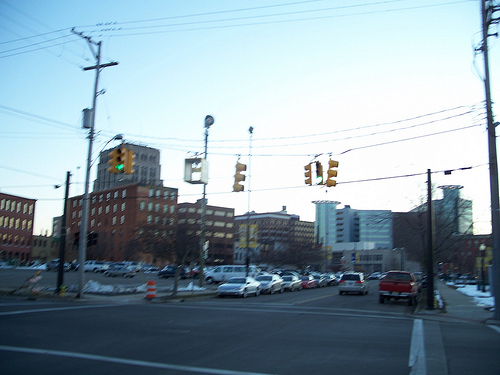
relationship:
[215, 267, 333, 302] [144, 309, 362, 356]
cars on street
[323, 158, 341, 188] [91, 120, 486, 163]
light hanging from wire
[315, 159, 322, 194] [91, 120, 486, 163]
light hanging from wire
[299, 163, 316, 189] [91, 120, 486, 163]
light hanging from wire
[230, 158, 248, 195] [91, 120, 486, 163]
light hanging from wire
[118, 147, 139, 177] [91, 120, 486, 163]
light hanging from wire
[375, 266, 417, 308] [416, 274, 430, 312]
truck parked at curb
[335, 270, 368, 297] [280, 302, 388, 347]
car driving down road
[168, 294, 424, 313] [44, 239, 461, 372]
line on road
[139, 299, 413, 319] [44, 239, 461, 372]
line on road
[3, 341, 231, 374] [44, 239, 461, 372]
line on road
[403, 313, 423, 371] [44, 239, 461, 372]
line on road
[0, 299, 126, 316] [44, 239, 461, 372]
line on road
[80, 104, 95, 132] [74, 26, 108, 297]
box on pole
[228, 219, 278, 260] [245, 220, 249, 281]
sign on pole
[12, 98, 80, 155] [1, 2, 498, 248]
clouds in sky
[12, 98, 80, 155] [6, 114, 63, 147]
clouds are white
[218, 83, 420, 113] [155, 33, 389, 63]
white cloud in blue sky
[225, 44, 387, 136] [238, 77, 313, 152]
clouds in sky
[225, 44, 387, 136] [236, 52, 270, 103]
clouds are blue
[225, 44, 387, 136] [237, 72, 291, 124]
clouds are white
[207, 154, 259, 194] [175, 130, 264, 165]
signal on wire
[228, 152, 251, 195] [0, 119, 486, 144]
traffic signal on wire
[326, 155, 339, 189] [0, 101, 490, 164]
signal on wire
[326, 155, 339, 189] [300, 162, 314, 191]
signal has light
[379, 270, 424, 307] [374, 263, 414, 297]
truck has red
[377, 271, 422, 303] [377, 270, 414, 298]
red truck has red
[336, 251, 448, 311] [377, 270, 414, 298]
truck has red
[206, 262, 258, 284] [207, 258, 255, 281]
van has white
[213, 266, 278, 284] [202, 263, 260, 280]
van has white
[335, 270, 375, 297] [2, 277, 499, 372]
car on road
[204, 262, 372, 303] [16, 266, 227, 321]
cars along sidewalk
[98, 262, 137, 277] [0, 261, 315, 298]
cars in parking lot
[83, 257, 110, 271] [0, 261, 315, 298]
cars in parking lot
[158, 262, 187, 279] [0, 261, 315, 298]
cars in parking lot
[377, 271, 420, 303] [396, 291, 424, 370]
red truck beside sidewalk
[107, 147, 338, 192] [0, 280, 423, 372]
traffic lights above street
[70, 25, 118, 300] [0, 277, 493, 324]
pole along sidewalk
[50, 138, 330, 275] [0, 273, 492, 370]
buildings beyond street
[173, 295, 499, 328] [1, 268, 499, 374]
lines on road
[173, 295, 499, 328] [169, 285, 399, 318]
lines are white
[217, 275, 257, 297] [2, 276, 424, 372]
car on road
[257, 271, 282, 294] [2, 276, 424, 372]
car on road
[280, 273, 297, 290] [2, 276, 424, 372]
car on road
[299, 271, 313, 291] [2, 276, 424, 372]
car on road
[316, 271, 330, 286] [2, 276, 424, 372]
car on road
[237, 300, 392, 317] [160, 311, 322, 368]
line on road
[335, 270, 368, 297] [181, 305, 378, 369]
car on road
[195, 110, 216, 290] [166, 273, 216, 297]
light pole on sidewalk